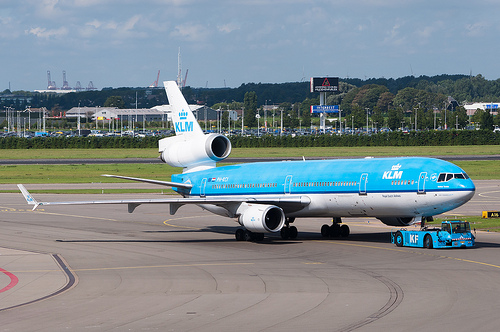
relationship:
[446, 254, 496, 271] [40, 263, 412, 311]
line on street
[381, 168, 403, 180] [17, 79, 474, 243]
logo on plane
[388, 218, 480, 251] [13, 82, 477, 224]
ground equipment towing plane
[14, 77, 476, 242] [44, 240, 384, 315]
airplane on ground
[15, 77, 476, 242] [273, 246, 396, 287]
airplane on ground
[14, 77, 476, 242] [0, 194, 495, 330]
airplane on ground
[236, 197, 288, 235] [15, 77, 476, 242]
engine on airplane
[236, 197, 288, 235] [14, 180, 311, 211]
engine on wing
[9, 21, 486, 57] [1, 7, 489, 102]
clouds in sky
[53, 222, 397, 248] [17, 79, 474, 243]
shadow of plane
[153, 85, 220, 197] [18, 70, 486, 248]
tail of plane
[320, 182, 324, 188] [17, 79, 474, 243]
window on plane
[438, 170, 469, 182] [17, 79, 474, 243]
windshield on plane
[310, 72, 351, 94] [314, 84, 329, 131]
sign on post